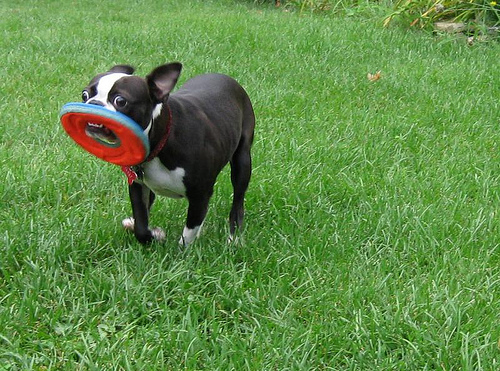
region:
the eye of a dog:
[111, 90, 130, 112]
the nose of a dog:
[86, 96, 105, 106]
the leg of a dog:
[176, 189, 214, 244]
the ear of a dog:
[144, 57, 186, 99]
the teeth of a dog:
[78, 120, 110, 129]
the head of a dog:
[68, 57, 185, 176]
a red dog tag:
[116, 160, 138, 188]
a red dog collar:
[139, 95, 181, 167]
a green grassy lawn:
[1, 0, 498, 367]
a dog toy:
[58, 95, 152, 170]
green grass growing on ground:
[293, 169, 497, 352]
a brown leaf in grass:
[360, 63, 390, 91]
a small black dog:
[39, 62, 314, 282]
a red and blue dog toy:
[55, 93, 147, 177]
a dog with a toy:
[53, 41, 315, 265]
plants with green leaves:
[410, 1, 497, 26]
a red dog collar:
[151, 101, 182, 161]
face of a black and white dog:
[72, 67, 159, 149]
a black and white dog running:
[38, 51, 315, 276]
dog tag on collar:
[117, 164, 139, 184]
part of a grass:
[418, 63, 461, 85]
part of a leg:
[128, 211, 158, 241]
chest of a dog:
[148, 165, 195, 180]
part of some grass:
[303, 266, 381, 337]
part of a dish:
[108, 127, 145, 184]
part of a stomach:
[206, 109, 241, 156]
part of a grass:
[323, 208, 366, 264]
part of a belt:
[151, 132, 168, 159]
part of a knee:
[233, 156, 255, 192]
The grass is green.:
[267, 42, 498, 369]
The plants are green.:
[292, 0, 492, 42]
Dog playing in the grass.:
[57, 52, 272, 257]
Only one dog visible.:
[57, 49, 272, 254]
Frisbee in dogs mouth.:
[48, 94, 158, 184]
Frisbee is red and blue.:
[55, 92, 152, 173]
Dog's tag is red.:
[109, 157, 139, 187]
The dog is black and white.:
[72, 55, 269, 251]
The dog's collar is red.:
[120, 92, 176, 184]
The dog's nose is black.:
[84, 94, 109, 112]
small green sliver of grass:
[180, 288, 210, 321]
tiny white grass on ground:
[375, 325, 446, 352]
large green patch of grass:
[285, 144, 462, 296]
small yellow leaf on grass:
[348, 44, 412, 102]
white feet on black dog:
[173, 214, 208, 267]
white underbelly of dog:
[135, 158, 219, 215]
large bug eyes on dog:
[47, 85, 144, 123]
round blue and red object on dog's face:
[42, 85, 171, 216]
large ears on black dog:
[98, 36, 213, 94]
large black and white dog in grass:
[44, 36, 359, 250]